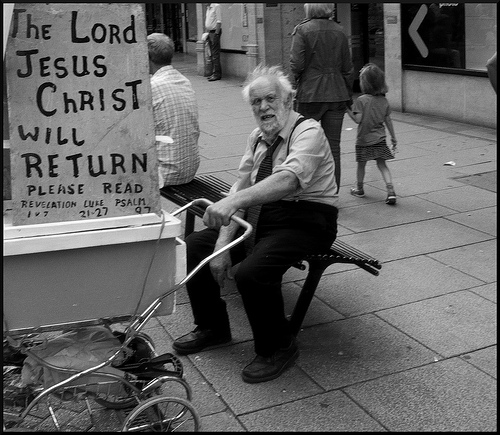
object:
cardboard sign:
[0, 0, 163, 229]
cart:
[0, 197, 254, 435]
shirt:
[225, 109, 341, 215]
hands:
[390, 137, 398, 151]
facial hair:
[250, 104, 257, 119]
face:
[248, 81, 285, 132]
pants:
[182, 199, 340, 358]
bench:
[156, 172, 382, 345]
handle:
[121, 197, 254, 345]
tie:
[241, 135, 287, 259]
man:
[170, 60, 341, 385]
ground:
[395, 127, 425, 177]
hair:
[241, 61, 293, 104]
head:
[239, 65, 296, 141]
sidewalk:
[109, 62, 499, 429]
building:
[151, 0, 500, 133]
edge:
[157, 184, 307, 273]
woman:
[287, 2, 357, 200]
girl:
[345, 62, 398, 205]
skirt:
[354, 138, 396, 163]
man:
[146, 31, 203, 194]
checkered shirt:
[147, 62, 202, 190]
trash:
[442, 159, 456, 166]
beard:
[252, 89, 289, 135]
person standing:
[199, 0, 224, 83]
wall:
[221, 2, 266, 81]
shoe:
[239, 334, 302, 386]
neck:
[258, 109, 303, 141]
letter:
[12, 48, 40, 79]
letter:
[70, 10, 90, 44]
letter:
[36, 81, 57, 117]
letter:
[20, 152, 43, 178]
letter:
[17, 124, 40, 142]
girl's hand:
[345, 101, 350, 112]